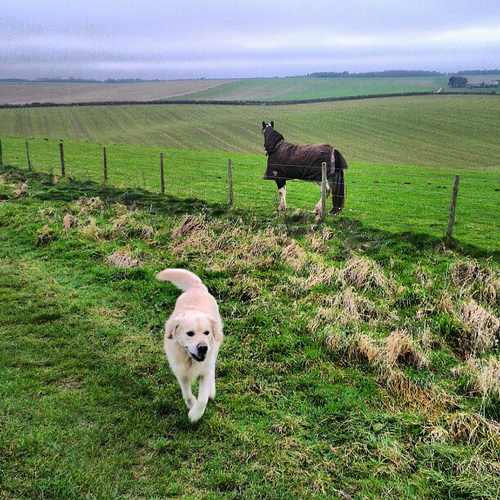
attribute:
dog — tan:
[138, 260, 245, 440]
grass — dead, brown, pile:
[311, 258, 403, 349]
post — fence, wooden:
[156, 149, 166, 195]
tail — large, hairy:
[318, 153, 366, 203]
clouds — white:
[0, 20, 499, 72]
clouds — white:
[21, 9, 351, 69]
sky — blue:
[2, 2, 486, 85]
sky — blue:
[114, 9, 239, 79]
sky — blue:
[119, 9, 237, 49]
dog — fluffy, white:
[139, 256, 235, 422]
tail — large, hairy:
[153, 267, 205, 286]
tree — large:
[446, 72, 474, 94]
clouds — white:
[245, 29, 351, 56]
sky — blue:
[2, 3, 490, 56]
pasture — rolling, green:
[64, 87, 495, 298]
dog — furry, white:
[153, 266, 225, 422]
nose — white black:
[195, 340, 208, 354]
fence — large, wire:
[0, 133, 497, 249]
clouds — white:
[21, 13, 496, 65]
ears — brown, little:
[257, 112, 274, 130]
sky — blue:
[6, 5, 493, 77]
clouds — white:
[13, 30, 492, 58]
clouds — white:
[6, 15, 490, 59]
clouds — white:
[7, 28, 497, 56]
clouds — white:
[9, 23, 491, 59]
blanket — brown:
[273, 138, 338, 178]